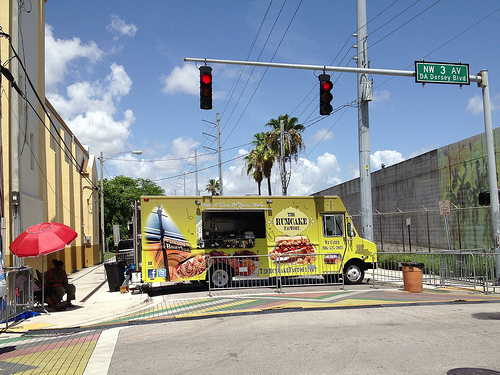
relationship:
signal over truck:
[199, 68, 212, 110] [135, 196, 378, 288]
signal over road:
[319, 75, 335, 116] [1, 288, 498, 375]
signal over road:
[199, 68, 212, 110] [1, 288, 498, 375]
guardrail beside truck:
[207, 252, 500, 296] [135, 196, 378, 288]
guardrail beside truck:
[209, 254, 346, 290] [135, 196, 378, 288]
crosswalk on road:
[139, 285, 497, 317] [1, 288, 498, 375]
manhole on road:
[446, 367, 500, 375] [1, 288, 498, 375]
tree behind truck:
[269, 115, 305, 200] [135, 196, 378, 288]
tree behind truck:
[252, 133, 279, 195] [135, 196, 378, 288]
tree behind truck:
[244, 151, 265, 195] [135, 196, 378, 288]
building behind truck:
[2, 0, 104, 286] [135, 196, 378, 288]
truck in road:
[135, 196, 378, 288] [1, 288, 498, 375]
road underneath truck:
[1, 288, 498, 375] [135, 196, 378, 288]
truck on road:
[135, 196, 378, 288] [1, 288, 498, 375]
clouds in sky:
[42, 24, 134, 158] [43, 1, 500, 195]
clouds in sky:
[108, 138, 340, 197] [43, 1, 500, 195]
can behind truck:
[103, 261, 125, 294] [135, 196, 378, 288]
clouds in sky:
[373, 149, 403, 170] [43, 1, 500, 195]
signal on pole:
[319, 75, 335, 116] [184, 57, 415, 76]